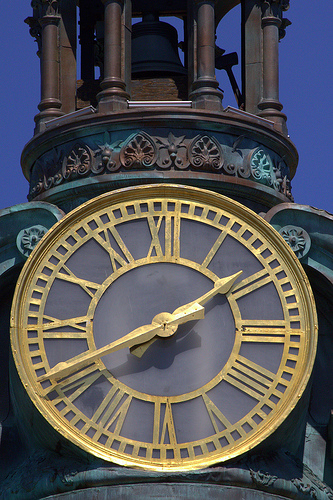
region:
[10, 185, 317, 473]
brown and grey clock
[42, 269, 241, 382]
wood arms on clock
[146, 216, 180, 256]
roman numeral number twelve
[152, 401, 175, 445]
roman numeral number six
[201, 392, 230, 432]
roman numeral number five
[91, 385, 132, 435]
roman numeral number seven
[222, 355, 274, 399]
roman numeral number four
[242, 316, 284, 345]
roman numeral number three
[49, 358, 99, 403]
roman numeral number eight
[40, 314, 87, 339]
roman numeral number nine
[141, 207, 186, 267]
The number twelve written in roman numeral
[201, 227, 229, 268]
The number one wrtiten in roman numeral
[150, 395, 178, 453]
The number six written in roman numerals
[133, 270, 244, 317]
The small hand on the clock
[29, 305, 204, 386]
The large hand on the clock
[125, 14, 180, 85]
The bell inside the tower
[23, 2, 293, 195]
The whole bell tower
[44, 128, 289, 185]
The blue on the decorative copper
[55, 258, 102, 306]
The number ten written in roman numerals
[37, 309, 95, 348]
The number nine written in roman numerals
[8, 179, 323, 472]
A large gold colored clock on a fixture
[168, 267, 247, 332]
The gold hour hand of the clock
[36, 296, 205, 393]
The gold minute hand of the clock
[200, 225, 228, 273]
The roman numeral I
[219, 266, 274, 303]
The roman numeral II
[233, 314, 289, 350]
The roman numeral III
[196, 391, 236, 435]
The roman numeral V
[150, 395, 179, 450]
The roman numeral VI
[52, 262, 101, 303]
The roman numeral X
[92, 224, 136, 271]
The roman numeral XI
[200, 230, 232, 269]
gold roman numeral one on a clock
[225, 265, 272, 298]
gold roman numeral two on a clock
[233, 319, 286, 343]
roman numeral three on a clock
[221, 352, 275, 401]
roman numeral four on a clock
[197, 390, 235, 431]
roman numeral five on a clock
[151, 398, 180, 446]
gold roman numeral six on a clock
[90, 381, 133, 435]
roman numeral seven on a clock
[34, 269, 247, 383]
gold hands on a clock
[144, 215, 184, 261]
gold roman numeral twelve on a clock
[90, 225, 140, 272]
gold roman numeral eleven on a clock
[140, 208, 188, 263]
The Roman numeral is gold.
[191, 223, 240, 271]
The Roman numeral is gold.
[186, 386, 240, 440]
The Roman numeral is gold.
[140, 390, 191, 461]
The Roman numeral is gold.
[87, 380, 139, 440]
The Roman numeral is gold.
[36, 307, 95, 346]
The Roman numeral is gold.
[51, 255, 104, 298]
The Roman numeral is gold.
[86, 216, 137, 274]
The Roman numeral is gold.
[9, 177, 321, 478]
The clock is round.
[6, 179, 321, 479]
The hands on the clock are gold.